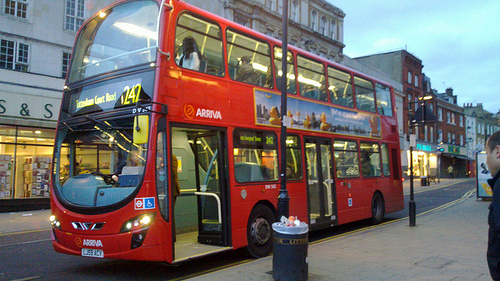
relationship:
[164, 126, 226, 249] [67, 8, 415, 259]
doorway of bus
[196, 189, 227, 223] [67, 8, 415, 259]
safety handle in bus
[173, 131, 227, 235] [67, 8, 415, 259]
door of bus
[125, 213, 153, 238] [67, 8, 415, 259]
headlight of bus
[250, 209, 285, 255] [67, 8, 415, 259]
tire of bus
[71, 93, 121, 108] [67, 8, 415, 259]
route of bus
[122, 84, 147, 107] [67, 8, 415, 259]
number of bus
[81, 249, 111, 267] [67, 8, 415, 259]
tag number of bus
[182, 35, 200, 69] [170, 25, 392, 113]
people in upper deck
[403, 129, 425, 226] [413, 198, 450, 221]
light post at curb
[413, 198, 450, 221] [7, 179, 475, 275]
curb of street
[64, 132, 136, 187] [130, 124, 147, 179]
windshield of driver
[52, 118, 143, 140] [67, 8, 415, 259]
windshield wipers of bus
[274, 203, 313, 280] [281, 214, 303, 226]
trash can full of trash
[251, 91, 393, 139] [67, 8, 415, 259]
picture on bus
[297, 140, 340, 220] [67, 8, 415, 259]
doors on bus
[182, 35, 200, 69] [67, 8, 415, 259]
people on bus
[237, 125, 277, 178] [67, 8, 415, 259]
window on bus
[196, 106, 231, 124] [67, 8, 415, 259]
letters on bus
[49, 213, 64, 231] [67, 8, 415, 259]
headlight of bus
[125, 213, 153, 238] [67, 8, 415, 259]
headlight on bus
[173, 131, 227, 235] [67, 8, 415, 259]
door on bus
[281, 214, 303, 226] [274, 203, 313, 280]
trash in trash can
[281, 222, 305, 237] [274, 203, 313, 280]
bag in trash can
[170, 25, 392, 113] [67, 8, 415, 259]
second level of bus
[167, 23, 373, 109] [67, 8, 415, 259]
windows of bus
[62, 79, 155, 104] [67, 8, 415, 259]
display on bus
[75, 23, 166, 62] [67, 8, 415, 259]
window of bus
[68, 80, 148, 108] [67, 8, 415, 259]
lights on bus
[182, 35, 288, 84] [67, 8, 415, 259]
people on bus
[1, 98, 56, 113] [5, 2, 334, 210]
letters on building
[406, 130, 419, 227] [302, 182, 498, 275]
street lamp on sidewalk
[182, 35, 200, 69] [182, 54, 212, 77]
people wearing shirt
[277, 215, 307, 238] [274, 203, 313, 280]
trash bag in trash can